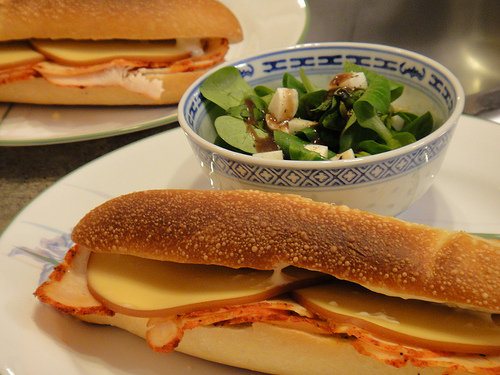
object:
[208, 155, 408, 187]
decoration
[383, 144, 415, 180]
design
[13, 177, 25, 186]
countertop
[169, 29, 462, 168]
salad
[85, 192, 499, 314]
bun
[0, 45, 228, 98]
meat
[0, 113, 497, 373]
white plate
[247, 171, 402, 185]
design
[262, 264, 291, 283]
mayo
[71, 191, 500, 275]
bread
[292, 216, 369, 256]
bread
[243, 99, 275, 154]
dressing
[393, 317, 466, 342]
cheese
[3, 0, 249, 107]
hoagie roll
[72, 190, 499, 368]
hoagie roll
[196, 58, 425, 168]
salad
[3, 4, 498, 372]
photo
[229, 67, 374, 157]
dressing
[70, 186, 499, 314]
bread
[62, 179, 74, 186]
plate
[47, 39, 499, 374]
food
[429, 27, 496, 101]
stainless steel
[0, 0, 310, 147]
plate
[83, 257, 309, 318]
cheese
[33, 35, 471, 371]
lunch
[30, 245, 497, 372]
meat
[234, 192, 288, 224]
seeds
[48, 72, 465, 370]
plate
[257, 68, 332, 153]
flower